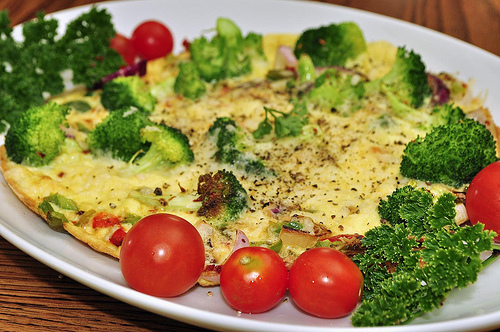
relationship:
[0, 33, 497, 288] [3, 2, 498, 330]
egg on an plate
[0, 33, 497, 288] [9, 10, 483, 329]
egg prepared cafe.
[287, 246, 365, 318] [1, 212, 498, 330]
tomato in foreground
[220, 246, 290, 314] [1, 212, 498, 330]
tomato in foreground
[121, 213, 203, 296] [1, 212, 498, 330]
cherry tomato in foreground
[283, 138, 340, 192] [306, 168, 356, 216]
seasoning on omelet.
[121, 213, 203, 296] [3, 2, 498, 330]
cherry tomato on plate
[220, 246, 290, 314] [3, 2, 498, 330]
tomato on plate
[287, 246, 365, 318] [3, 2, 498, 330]
tomato on plate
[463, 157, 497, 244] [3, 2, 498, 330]
tomato on side of plate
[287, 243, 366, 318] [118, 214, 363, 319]
tomato on right of row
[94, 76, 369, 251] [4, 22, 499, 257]
ham on pizza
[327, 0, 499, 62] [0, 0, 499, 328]
corner on table